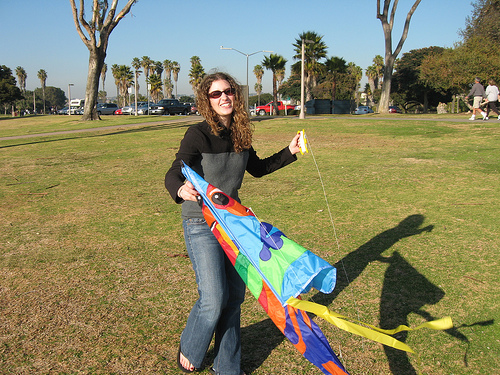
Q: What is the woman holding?
A: A kite.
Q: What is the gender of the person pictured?
A: Female.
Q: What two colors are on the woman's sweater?
A: Black and grey.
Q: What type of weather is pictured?
A: Sunny and clear.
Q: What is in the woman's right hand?
A: Kite.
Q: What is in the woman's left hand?
A: Kite string.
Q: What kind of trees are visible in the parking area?
A: Palm trees.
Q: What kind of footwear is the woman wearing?
A: Flip flops.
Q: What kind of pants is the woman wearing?
A: Blue jeans.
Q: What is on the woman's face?
A: Sunglasses.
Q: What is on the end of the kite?
A: Yellow streamers.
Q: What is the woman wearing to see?
A: Sunglasses.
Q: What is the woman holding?
A: Kite.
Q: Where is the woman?
A: Park.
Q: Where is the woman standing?
A: Field.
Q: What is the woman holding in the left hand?
A: Roll of string.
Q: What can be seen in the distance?
A: Trees.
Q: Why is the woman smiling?
A: Having fun.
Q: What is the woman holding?
A: A kite.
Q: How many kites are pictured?
A: One.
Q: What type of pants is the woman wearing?
A: Blue jeans.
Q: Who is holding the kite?
A: The woman.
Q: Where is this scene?
A: In a park.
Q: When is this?
A: During the day.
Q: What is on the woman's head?
A: Sunglasses.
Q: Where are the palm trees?
A: Behind the woman.